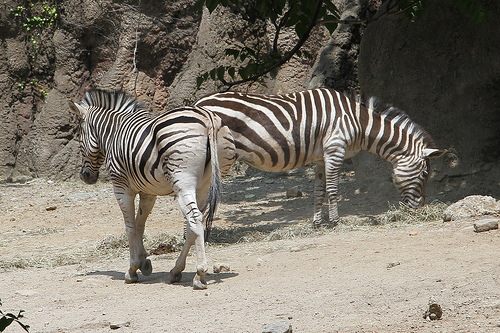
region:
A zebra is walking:
[74, 86, 216, 287]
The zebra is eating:
[194, 89, 448, 227]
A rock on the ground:
[472, 216, 496, 231]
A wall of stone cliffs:
[0, 0, 499, 177]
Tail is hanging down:
[202, 126, 220, 233]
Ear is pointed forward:
[422, 147, 446, 158]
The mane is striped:
[80, 89, 139, 113]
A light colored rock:
[262, 321, 290, 331]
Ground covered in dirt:
[1, 181, 498, 331]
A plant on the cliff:
[11, 6, 57, 98]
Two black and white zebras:
[68, 85, 444, 290]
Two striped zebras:
[69, 82, 444, 289]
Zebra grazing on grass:
[180, 87, 443, 242]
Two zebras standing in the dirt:
[66, 80, 447, 295]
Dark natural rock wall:
[0, 0, 497, 184]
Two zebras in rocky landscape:
[0, 0, 495, 332]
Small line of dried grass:
[0, 199, 463, 274]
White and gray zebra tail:
[202, 117, 223, 241]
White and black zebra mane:
[75, 85, 142, 113]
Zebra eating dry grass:
[181, 86, 448, 241]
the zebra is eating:
[376, 90, 461, 245]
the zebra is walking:
[47, 57, 254, 314]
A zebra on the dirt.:
[68, 85, 237, 289]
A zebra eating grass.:
[194, 87, 448, 229]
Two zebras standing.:
[68, 86, 450, 291]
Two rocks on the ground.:
[440, 193, 499, 232]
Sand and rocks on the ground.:
[1, 168, 498, 330]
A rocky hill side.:
[3, 0, 498, 202]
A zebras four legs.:
[113, 171, 215, 291]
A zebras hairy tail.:
[206, 122, 228, 245]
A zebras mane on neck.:
[342, 87, 440, 149]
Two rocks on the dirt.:
[441, 193, 498, 233]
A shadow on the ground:
[86, 270, 235, 284]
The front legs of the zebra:
[113, 185, 153, 279]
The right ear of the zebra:
[423, 145, 444, 160]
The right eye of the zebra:
[416, 166, 433, 178]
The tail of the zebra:
[206, 118, 219, 230]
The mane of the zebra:
[353, 91, 430, 146]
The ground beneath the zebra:
[5, 174, 492, 331]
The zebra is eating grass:
[188, 91, 445, 223]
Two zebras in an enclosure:
[66, 87, 441, 289]